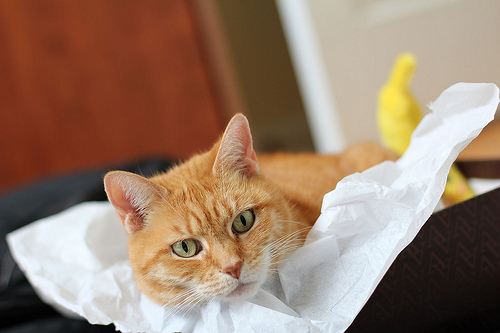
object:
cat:
[104, 112, 403, 315]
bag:
[6, 81, 499, 332]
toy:
[375, 53, 470, 203]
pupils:
[178, 242, 194, 254]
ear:
[211, 111, 255, 176]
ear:
[102, 168, 163, 230]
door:
[0, 1, 226, 192]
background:
[0, 0, 498, 193]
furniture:
[345, 160, 500, 333]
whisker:
[171, 293, 211, 310]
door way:
[0, 0, 321, 177]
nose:
[222, 258, 244, 280]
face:
[129, 172, 288, 307]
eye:
[229, 207, 255, 234]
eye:
[170, 236, 203, 260]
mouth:
[226, 278, 255, 297]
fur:
[171, 188, 225, 217]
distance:
[0, 0, 498, 224]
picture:
[1, 0, 498, 333]